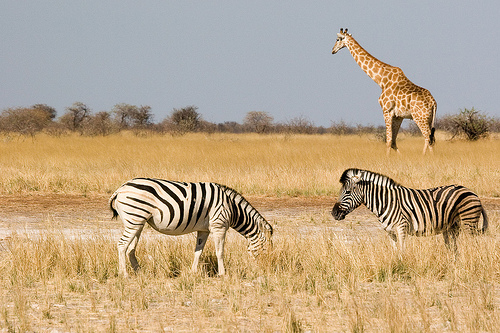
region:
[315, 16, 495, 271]
a giraffe and a zebra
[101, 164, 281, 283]
zebra with head down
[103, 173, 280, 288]
zebra grazing in brush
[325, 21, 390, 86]
profile of giraffe's head and neck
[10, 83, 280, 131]
tree line along horizon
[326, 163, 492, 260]
black and white zebra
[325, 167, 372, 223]
profile of a zebra's head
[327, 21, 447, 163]
giraffe standing in brush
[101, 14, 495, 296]
three animals in a field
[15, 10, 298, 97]
gray sky without clouds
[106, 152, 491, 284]
TWO ZEBRAS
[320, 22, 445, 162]
A TALL GIRAFFE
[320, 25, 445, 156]
THIS IS A GIRAFFE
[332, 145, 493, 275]
THIS IS A ZEBRA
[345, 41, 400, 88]
THE GIRAFFE HAS A LONG NECK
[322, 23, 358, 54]
THIS IS A GIRAFFES HEAD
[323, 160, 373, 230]
THIS IS A ZEBRAS HEAD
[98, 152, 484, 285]
THE ZEBRAS HAVE STRIPES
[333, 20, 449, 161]
THE GIRAFFE HAS ORANGE SPOTS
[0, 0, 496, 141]
THE HAZY SKY IS GREYISH BLUE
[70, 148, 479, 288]
Two zebras in the field.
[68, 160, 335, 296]
A zebra eating grass.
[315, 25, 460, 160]
A tall giraffe in the field.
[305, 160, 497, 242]
The zebra is standing in the grass.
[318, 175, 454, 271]
The zebra is black and white.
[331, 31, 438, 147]
The giraffe is brown and white.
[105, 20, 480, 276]
Animals standing in the wilderness.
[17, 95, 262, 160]
Trees in the background.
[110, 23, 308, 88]
The sky is blue.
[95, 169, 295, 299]
The zebra is bent over.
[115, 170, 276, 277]
black and white zebra on plain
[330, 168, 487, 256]
black and white zebra on plain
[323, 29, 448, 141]
tan and brown giraffe on plain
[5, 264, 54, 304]
tall yellow grass on plain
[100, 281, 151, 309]
tall yellow grass on plain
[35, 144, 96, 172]
tall yellow grass on plain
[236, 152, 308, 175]
tall yellow grass on plain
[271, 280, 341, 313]
tall yellow grass on plain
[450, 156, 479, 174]
tall yellow grass on plain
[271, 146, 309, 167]
tall yellow grass on plain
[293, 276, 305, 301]
part of the grass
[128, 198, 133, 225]
back of a zebra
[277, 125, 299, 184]
part of a plain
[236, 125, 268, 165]
part of a plantation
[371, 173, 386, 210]
neck of a zebra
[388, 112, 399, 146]
leg of a giraffe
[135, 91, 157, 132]
edge of a branch